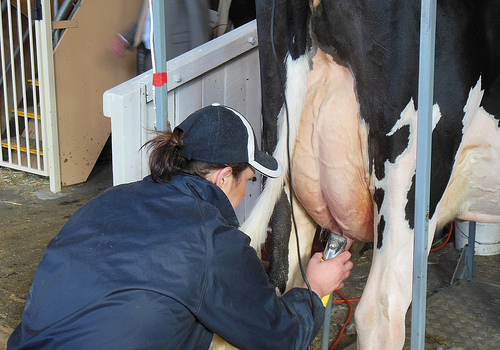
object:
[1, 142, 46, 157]
yellow stripe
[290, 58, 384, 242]
glands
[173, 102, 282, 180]
cap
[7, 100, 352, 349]
woman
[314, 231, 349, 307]
device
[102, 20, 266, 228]
white area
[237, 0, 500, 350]
cow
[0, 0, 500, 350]
barn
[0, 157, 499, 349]
floor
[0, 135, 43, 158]
stair